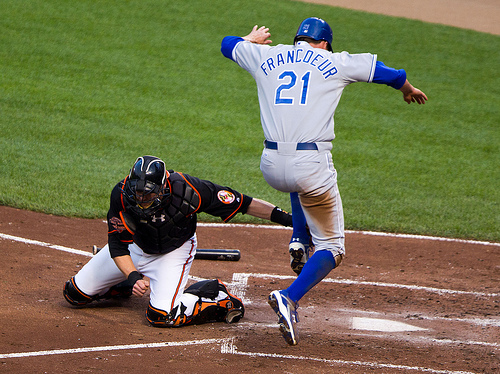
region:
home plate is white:
[348, 312, 435, 337]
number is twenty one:
[271, 69, 312, 108]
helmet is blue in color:
[291, 14, 339, 51]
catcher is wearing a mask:
[60, 156, 297, 324]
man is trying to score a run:
[218, 14, 429, 345]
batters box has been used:
[221, 265, 498, 372]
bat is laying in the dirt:
[86, 244, 249, 261]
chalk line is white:
[0, 332, 235, 363]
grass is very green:
[0, 0, 496, 240]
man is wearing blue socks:
[218, 13, 432, 343]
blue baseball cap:
[286, 10, 337, 54]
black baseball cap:
[122, 150, 173, 220]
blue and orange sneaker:
[261, 286, 306, 349]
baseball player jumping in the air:
[216, 10, 432, 350]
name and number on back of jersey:
[259, 44, 340, 111]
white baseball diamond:
[343, 307, 436, 344]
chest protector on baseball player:
[113, 166, 203, 236]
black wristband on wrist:
[265, 200, 297, 230]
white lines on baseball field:
[1, 332, 491, 372]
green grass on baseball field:
[2, 0, 497, 251]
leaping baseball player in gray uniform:
[213, 12, 439, 354]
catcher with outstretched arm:
[43, 142, 305, 342]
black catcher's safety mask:
[115, 171, 175, 221]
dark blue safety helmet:
[289, 12, 336, 52]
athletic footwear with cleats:
[260, 235, 317, 348]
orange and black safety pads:
[141, 298, 246, 330]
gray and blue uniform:
[211, 28, 410, 307]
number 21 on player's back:
[269, 65, 316, 115]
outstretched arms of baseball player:
[214, 19, 431, 114]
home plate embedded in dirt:
[342, 310, 436, 339]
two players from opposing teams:
[53, 18, 429, 353]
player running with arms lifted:
[220, 15, 430, 345]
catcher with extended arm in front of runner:
[60, 145, 345, 340]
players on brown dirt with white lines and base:
[5, 16, 495, 358]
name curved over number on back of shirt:
[231, 37, 371, 137]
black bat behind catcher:
[106, 146, 258, 326]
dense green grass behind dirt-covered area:
[2, 0, 487, 365]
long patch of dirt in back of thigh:
[291, 165, 347, 260]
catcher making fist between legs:
[65, 233, 195, 321]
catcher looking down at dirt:
[67, 140, 205, 361]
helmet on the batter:
[288, 6, 344, 46]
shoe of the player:
[242, 265, 324, 356]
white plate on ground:
[342, 299, 434, 359]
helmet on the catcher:
[103, 149, 187, 225]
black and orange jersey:
[196, 171, 256, 238]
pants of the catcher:
[43, 234, 213, 333]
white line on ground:
[77, 317, 137, 369]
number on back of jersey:
[258, 65, 327, 114]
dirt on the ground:
[371, 242, 459, 281]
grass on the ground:
[371, 157, 471, 219]